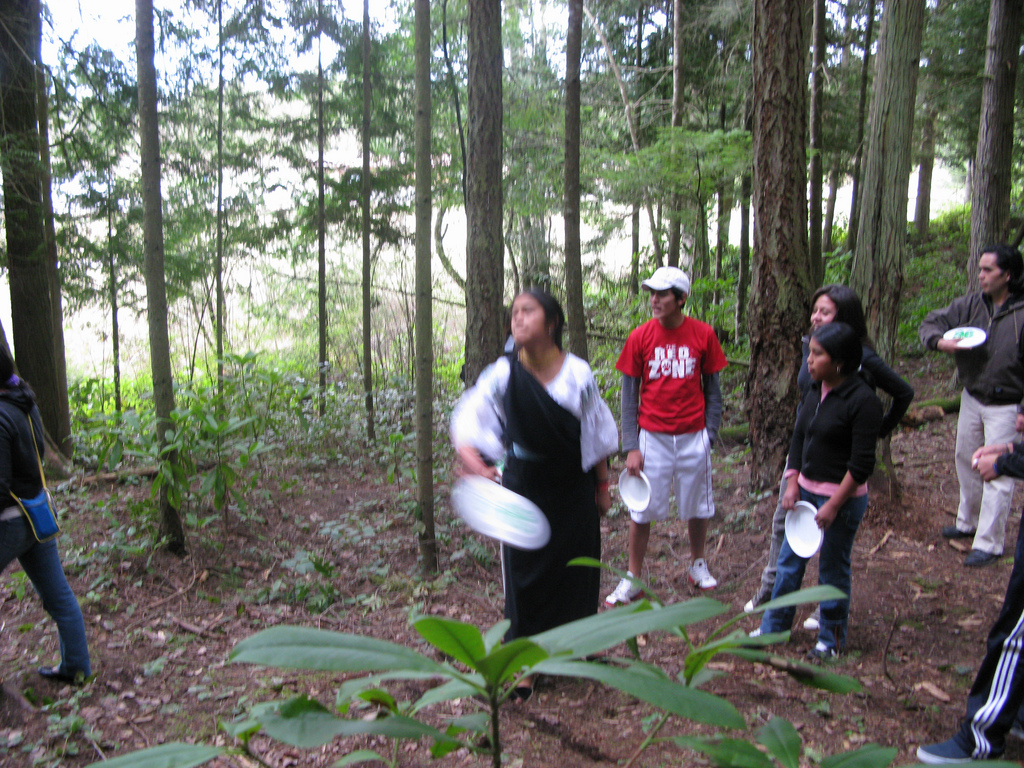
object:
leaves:
[583, 656, 751, 735]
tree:
[0, 0, 157, 468]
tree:
[669, 8, 754, 388]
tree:
[848, 8, 928, 336]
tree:
[955, 11, 1020, 247]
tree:
[458, 11, 516, 386]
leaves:
[361, 45, 428, 102]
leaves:
[589, 95, 644, 138]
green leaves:
[595, 124, 705, 178]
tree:
[602, 0, 741, 296]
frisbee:
[784, 500, 826, 558]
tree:
[568, 0, 669, 314]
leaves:
[58, 30, 105, 46]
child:
[742, 328, 883, 660]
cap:
[642, 266, 691, 295]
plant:
[534, 587, 706, 671]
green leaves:
[158, 48, 202, 116]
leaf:
[715, 128, 750, 166]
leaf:
[608, 149, 635, 166]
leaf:
[521, 92, 548, 116]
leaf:
[378, 220, 413, 252]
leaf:
[295, 191, 314, 221]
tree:
[299, 4, 338, 425]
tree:
[354, 9, 397, 449]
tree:
[260, 7, 360, 408]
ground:
[5, 357, 1024, 766]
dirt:
[5, 354, 1021, 766]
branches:
[5, 668, 114, 766]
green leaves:
[98, 89, 130, 143]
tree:
[104, 0, 218, 420]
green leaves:
[97, 224, 138, 284]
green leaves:
[317, 10, 359, 44]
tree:
[258, 4, 414, 418]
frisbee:
[451, 475, 550, 548]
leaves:
[232, 598, 420, 676]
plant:
[238, 554, 681, 758]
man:
[607, 262, 725, 599]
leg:
[955, 541, 1023, 751]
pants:
[948, 574, 1020, 752]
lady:
[447, 282, 622, 666]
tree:
[184, 1, 279, 420]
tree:
[904, 8, 1024, 328]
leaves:
[732, 574, 855, 653]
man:
[929, 244, 1024, 562]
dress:
[489, 344, 596, 636]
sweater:
[781, 370, 879, 491]